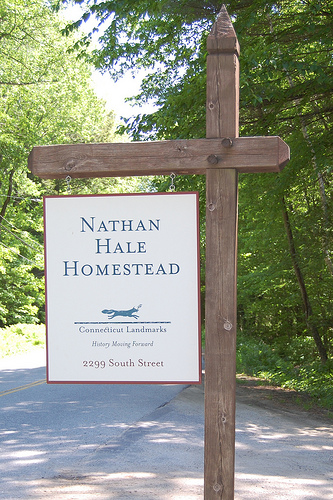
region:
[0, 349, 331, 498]
a paved road near a forest.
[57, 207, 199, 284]
a sign advertising a neighborhood.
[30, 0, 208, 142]
a section of a hazy blue sky.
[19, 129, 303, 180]
a board with a sign on it.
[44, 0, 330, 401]
a forest of leafy green trees.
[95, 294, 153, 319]
a company logo.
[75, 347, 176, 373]
a street sign on a board.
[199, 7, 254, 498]
a wooden post with a sign.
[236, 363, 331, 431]
a section of dirt near a road.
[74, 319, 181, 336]
a sign with words.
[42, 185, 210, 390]
a sign on a wooden stake.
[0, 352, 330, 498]
a paved road near a field.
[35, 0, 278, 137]
a hazy blue sky.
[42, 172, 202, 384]
a homestead sign.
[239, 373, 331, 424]
dirt on the side of a road.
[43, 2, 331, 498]
a forest filled with leafy trees.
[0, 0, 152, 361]
a forest filled with leafy trees.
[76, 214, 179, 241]
the name nathan on a sign.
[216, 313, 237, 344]
a knot on wood.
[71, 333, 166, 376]
a street sign.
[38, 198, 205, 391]
A sign for Nathan Hale Homestead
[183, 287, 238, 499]
A wooden pole holding sign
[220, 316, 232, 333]
Small knot on the post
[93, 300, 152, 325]
Decal of a fox on sign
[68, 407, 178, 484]
Crack on the road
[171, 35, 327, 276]
Group of trees beside road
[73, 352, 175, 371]
The address is on South Street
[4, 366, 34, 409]
Yellow paint on the road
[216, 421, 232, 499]
Small crack in the post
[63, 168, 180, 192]
Chain holding sign up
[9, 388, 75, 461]
this is the road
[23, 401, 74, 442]
the road is clear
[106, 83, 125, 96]
this is the sky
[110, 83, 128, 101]
the sky is blue in color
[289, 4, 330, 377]
this is a tree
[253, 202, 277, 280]
the leaves are green in color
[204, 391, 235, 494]
this is a pole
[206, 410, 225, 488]
the pole is wooden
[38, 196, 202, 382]
this is a signboard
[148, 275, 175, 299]
the signboard is white in color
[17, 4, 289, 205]
top of wooden sign post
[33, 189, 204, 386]
sign announcing this location is a historic landmark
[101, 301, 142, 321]
s blue fox running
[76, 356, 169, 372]
the street address of the landmark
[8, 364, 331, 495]
shadows on the road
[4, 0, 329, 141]
the green tree tops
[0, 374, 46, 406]
double yellow line down center of the road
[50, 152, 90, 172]
a know in the wood of the post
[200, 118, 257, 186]
bolts to hold the two pieces of post together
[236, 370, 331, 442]
bare spot of earth below trees